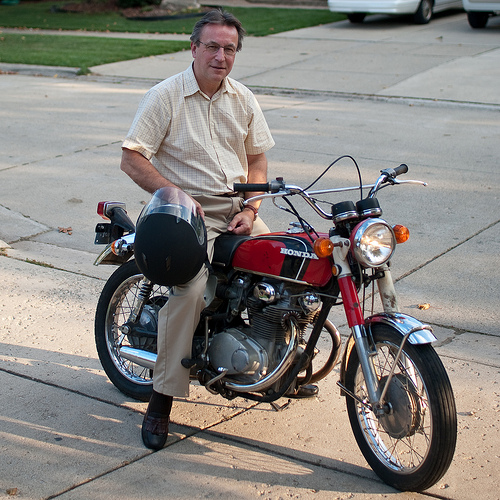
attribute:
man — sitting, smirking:
[117, 8, 327, 449]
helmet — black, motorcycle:
[132, 184, 211, 291]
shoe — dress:
[141, 394, 171, 448]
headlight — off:
[352, 218, 396, 268]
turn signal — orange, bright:
[392, 222, 411, 244]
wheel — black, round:
[343, 313, 459, 493]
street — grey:
[0, 65, 499, 341]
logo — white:
[275, 244, 324, 262]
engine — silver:
[220, 272, 323, 363]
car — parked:
[326, 0, 470, 25]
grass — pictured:
[2, 1, 346, 69]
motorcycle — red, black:
[83, 150, 460, 496]